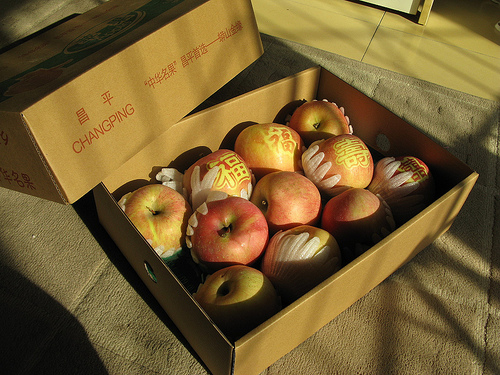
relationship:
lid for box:
[0, 1, 265, 205] [93, 64, 479, 375]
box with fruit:
[93, 64, 479, 375] [125, 99, 439, 334]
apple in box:
[192, 196, 268, 268] [93, 64, 479, 375]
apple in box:
[198, 265, 280, 338] [93, 64, 479, 375]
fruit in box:
[125, 99, 439, 334] [93, 64, 479, 375]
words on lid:
[72, 21, 244, 153] [0, 1, 265, 205]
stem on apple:
[221, 225, 232, 239] [192, 196, 268, 268]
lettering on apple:
[207, 151, 252, 190] [182, 149, 253, 200]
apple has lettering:
[182, 149, 253, 200] [207, 151, 252, 190]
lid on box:
[0, 1, 265, 205] [93, 64, 479, 375]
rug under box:
[1, 1, 500, 375] [93, 64, 479, 375]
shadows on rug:
[2, 1, 498, 374] [1, 1, 500, 375]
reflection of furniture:
[399, 25, 429, 73] [343, 0, 435, 27]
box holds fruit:
[93, 64, 479, 375] [125, 99, 439, 334]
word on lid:
[73, 102, 135, 153] [0, 1, 265, 205]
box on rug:
[93, 64, 479, 375] [1, 1, 500, 375]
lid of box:
[0, 1, 265, 205] [93, 64, 479, 375]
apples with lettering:
[183, 124, 434, 205] [207, 124, 430, 206]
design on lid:
[0, 1, 181, 102] [0, 1, 265, 205]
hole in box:
[141, 259, 158, 284] [93, 64, 479, 375]